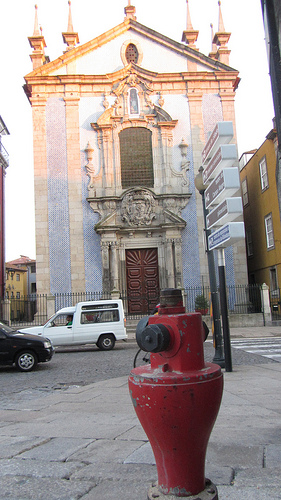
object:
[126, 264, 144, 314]
door